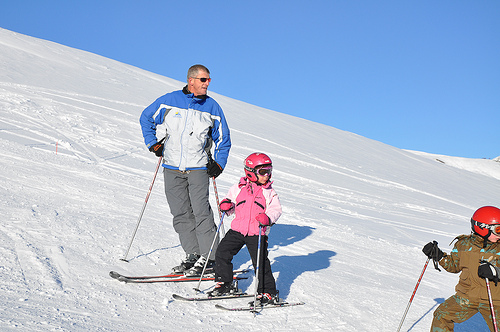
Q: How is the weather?
A: It is clear.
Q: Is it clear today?
A: Yes, it is clear.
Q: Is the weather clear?
A: Yes, it is clear.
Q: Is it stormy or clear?
A: It is clear.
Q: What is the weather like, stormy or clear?
A: It is clear.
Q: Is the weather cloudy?
A: No, it is clear.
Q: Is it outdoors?
A: Yes, it is outdoors.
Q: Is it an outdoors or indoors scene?
A: It is outdoors.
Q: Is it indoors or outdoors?
A: It is outdoors.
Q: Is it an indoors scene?
A: No, it is outdoors.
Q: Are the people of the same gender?
A: No, they are both male and female.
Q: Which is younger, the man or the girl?
A: The girl is younger than the man.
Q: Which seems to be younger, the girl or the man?
A: The girl is younger than the man.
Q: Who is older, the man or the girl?
A: The man is older than the girl.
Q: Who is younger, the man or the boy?
A: The boy is younger than the man.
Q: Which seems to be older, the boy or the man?
A: The man is older than the boy.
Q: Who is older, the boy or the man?
A: The man is older than the boy.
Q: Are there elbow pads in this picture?
A: No, there are no elbow pads.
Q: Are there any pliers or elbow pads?
A: No, there are no elbow pads or pliers.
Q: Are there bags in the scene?
A: No, there are no bags.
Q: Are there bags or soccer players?
A: No, there are no bags or soccer players.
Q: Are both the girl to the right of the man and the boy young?
A: Yes, both the girl and the boy are young.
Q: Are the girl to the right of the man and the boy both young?
A: Yes, both the girl and the boy are young.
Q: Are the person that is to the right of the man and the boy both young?
A: Yes, both the girl and the boy are young.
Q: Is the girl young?
A: Yes, the girl is young.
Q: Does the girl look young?
A: Yes, the girl is young.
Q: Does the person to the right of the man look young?
A: Yes, the girl is young.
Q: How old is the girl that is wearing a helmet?
A: The girl is young.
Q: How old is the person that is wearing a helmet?
A: The girl is young.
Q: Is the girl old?
A: No, the girl is young.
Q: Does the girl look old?
A: No, the girl is young.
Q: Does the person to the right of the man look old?
A: No, the girl is young.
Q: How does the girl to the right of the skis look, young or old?
A: The girl is young.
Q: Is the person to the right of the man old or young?
A: The girl is young.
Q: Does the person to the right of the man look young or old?
A: The girl is young.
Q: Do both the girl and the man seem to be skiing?
A: Yes, both the girl and the man are skiing.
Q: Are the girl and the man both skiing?
A: Yes, both the girl and the man are skiing.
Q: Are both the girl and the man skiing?
A: Yes, both the girl and the man are skiing.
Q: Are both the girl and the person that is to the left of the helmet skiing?
A: Yes, both the girl and the man are skiing.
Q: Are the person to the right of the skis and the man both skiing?
A: Yes, both the girl and the man are skiing.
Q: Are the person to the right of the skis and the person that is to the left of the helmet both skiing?
A: Yes, both the girl and the man are skiing.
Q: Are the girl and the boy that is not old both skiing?
A: Yes, both the girl and the boy are skiing.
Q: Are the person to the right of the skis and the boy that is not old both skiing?
A: Yes, both the girl and the boy are skiing.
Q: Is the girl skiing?
A: Yes, the girl is skiing.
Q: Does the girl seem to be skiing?
A: Yes, the girl is skiing.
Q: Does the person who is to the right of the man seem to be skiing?
A: Yes, the girl is skiing.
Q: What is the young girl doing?
A: The girl is skiing.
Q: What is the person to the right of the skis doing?
A: The girl is skiing.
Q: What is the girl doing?
A: The girl is skiing.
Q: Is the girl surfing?
A: No, the girl is skiing.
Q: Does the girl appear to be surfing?
A: No, the girl is skiing.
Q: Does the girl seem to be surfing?
A: No, the girl is skiing.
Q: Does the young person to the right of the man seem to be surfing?
A: No, the girl is skiing.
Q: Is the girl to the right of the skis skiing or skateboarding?
A: The girl is skiing.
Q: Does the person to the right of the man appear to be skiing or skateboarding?
A: The girl is skiing.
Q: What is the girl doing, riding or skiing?
A: The girl is skiing.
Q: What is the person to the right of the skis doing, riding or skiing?
A: The girl is skiing.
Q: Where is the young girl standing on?
A: The girl is standing on the ground.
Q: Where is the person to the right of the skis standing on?
A: The girl is standing on the ground.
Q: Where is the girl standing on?
A: The girl is standing on the ground.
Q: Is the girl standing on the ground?
A: Yes, the girl is standing on the ground.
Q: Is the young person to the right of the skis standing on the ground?
A: Yes, the girl is standing on the ground.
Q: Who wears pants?
A: The girl wears pants.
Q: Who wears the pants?
A: The girl wears pants.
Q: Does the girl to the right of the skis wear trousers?
A: Yes, the girl wears trousers.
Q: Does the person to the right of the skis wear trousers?
A: Yes, the girl wears trousers.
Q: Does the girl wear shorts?
A: No, the girl wears trousers.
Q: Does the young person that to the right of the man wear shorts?
A: No, the girl wears trousers.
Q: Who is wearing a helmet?
A: The girl is wearing a helmet.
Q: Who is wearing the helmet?
A: The girl is wearing a helmet.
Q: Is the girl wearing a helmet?
A: Yes, the girl is wearing a helmet.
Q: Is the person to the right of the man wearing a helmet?
A: Yes, the girl is wearing a helmet.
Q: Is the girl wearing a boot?
A: No, the girl is wearing a helmet.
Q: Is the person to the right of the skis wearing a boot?
A: No, the girl is wearing a helmet.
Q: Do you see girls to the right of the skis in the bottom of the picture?
A: Yes, there is a girl to the right of the skis.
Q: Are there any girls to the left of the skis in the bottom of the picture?
A: No, the girl is to the right of the skis.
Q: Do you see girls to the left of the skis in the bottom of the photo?
A: No, the girl is to the right of the skis.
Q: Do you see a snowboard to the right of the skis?
A: No, there is a girl to the right of the skis.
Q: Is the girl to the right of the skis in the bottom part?
A: Yes, the girl is to the right of the skis.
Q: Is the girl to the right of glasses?
A: No, the girl is to the right of the skis.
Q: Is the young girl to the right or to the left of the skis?
A: The girl is to the right of the skis.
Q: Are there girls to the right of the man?
A: Yes, there is a girl to the right of the man.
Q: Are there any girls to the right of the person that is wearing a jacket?
A: Yes, there is a girl to the right of the man.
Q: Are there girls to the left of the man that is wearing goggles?
A: No, the girl is to the right of the man.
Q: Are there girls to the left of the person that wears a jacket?
A: No, the girl is to the right of the man.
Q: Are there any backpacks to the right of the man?
A: No, there is a girl to the right of the man.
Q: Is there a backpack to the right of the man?
A: No, there is a girl to the right of the man.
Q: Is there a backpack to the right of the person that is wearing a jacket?
A: No, there is a girl to the right of the man.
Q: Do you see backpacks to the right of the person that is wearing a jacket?
A: No, there is a girl to the right of the man.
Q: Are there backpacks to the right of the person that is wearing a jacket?
A: No, there is a girl to the right of the man.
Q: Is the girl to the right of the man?
A: Yes, the girl is to the right of the man.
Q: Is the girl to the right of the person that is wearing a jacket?
A: Yes, the girl is to the right of the man.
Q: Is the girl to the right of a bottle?
A: No, the girl is to the right of the man.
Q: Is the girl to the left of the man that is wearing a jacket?
A: No, the girl is to the right of the man.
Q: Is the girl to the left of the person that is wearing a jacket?
A: No, the girl is to the right of the man.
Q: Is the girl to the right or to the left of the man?
A: The girl is to the right of the man.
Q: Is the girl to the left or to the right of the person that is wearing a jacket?
A: The girl is to the right of the man.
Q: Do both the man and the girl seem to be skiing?
A: Yes, both the man and the girl are skiing.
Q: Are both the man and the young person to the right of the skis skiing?
A: Yes, both the man and the girl are skiing.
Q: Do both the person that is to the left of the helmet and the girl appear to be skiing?
A: Yes, both the man and the girl are skiing.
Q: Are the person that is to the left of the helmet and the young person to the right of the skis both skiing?
A: Yes, both the man and the girl are skiing.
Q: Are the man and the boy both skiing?
A: Yes, both the man and the boy are skiing.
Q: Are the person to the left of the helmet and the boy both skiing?
A: Yes, both the man and the boy are skiing.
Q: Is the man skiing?
A: Yes, the man is skiing.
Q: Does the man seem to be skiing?
A: Yes, the man is skiing.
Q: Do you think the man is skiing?
A: Yes, the man is skiing.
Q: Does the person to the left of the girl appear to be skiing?
A: Yes, the man is skiing.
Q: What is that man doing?
A: The man is skiing.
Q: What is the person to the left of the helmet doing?
A: The man is skiing.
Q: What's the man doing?
A: The man is skiing.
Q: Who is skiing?
A: The man is skiing.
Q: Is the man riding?
A: No, the man is skiing.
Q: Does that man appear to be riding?
A: No, the man is skiing.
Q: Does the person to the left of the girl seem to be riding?
A: No, the man is skiing.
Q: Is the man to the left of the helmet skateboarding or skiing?
A: The man is skiing.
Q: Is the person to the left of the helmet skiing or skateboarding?
A: The man is skiing.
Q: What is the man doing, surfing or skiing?
A: The man is skiing.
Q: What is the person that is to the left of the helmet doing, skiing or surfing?
A: The man is skiing.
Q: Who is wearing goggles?
A: The man is wearing goggles.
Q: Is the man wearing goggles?
A: Yes, the man is wearing goggles.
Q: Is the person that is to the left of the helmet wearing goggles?
A: Yes, the man is wearing goggles.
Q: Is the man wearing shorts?
A: No, the man is wearing goggles.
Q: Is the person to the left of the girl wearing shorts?
A: No, the man is wearing goggles.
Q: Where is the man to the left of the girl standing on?
A: The man is standing on the ground.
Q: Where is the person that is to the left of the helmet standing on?
A: The man is standing on the ground.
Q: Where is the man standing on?
A: The man is standing on the ground.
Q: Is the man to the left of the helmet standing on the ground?
A: Yes, the man is standing on the ground.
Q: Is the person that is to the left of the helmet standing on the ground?
A: Yes, the man is standing on the ground.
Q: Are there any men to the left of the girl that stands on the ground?
A: Yes, there is a man to the left of the girl.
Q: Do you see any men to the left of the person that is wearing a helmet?
A: Yes, there is a man to the left of the girl.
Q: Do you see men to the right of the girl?
A: No, the man is to the left of the girl.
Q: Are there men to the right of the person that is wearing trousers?
A: No, the man is to the left of the girl.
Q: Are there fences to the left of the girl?
A: No, there is a man to the left of the girl.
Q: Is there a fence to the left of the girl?
A: No, there is a man to the left of the girl.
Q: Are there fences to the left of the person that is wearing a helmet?
A: No, there is a man to the left of the girl.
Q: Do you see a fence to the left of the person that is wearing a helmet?
A: No, there is a man to the left of the girl.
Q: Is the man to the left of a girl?
A: Yes, the man is to the left of a girl.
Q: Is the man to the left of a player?
A: No, the man is to the left of a girl.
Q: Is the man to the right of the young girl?
A: No, the man is to the left of the girl.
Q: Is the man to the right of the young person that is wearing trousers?
A: No, the man is to the left of the girl.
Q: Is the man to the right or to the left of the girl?
A: The man is to the left of the girl.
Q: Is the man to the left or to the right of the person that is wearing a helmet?
A: The man is to the left of the girl.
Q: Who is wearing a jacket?
A: The man is wearing a jacket.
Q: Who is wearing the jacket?
A: The man is wearing a jacket.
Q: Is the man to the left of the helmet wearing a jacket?
A: Yes, the man is wearing a jacket.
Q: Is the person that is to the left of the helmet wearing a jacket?
A: Yes, the man is wearing a jacket.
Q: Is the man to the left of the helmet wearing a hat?
A: No, the man is wearing a jacket.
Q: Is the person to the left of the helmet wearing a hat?
A: No, the man is wearing a jacket.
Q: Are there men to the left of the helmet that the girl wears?
A: Yes, there is a man to the left of the helmet.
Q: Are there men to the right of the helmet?
A: No, the man is to the left of the helmet.